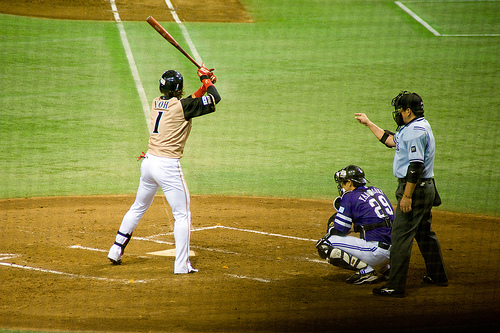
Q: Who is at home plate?
A: A player.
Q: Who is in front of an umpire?
A: A catcher.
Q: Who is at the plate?
A: A baseball player.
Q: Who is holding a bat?
A: A baseball player.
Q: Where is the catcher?
A: Behind the plate.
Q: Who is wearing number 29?
A: Catcher.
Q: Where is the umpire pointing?
A: Toward the pitcher.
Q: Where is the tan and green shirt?
A: On the batter.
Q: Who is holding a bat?
A: The batter.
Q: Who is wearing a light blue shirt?
A: The umpire.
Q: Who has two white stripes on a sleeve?
A: Catcher.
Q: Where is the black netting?
A: Front of entire scene.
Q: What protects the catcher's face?
A: A mask.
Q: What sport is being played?
A: Baseball.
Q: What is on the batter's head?
A: A helmet.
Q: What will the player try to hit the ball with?
A: A bat.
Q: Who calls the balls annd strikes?
A: The umpire.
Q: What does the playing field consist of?
A: Grass and dirt.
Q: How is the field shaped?
A: Like a diamond.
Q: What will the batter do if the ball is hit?
A: Run.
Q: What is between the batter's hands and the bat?
A: Gloves.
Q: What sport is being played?
A: Baseball.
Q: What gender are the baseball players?
A: Male.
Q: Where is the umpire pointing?
A: At the batter.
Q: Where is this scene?
A: A ballpark.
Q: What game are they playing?
A: Baseball.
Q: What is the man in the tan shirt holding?
A: A bat.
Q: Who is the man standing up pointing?
A: The umpire.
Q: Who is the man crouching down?
A: The Catcher.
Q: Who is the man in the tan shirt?
A: The Batter.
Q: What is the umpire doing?
A: Pointing.